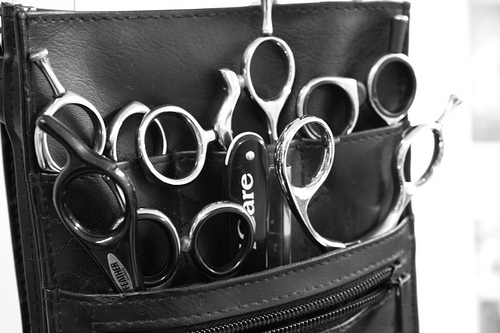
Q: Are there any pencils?
A: No, there are no pencils.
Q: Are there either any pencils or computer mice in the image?
A: No, there are no pencils or computer mice.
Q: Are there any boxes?
A: No, there are no boxes.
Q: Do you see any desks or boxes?
A: No, there are no boxes or desks.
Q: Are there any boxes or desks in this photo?
A: No, there are no boxes or desks.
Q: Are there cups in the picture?
A: No, there are no cups.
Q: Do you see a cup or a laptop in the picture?
A: No, there are no cups or laptops.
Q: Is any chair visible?
A: No, there are no chairs.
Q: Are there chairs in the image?
A: No, there are no chairs.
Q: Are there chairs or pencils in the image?
A: No, there are no chairs or pencils.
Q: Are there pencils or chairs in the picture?
A: No, there are no chairs or pencils.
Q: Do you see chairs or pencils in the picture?
A: No, there are no chairs or pencils.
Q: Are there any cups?
A: No, there are no cups.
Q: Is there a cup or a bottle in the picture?
A: No, there are no cups or bottles.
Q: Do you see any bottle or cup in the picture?
A: No, there are no cups or bottles.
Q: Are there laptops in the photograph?
A: No, there are no laptops.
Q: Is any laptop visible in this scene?
A: No, there are no laptops.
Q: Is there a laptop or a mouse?
A: No, there are no laptops or computer mice.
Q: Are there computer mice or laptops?
A: No, there are no laptops or computer mice.